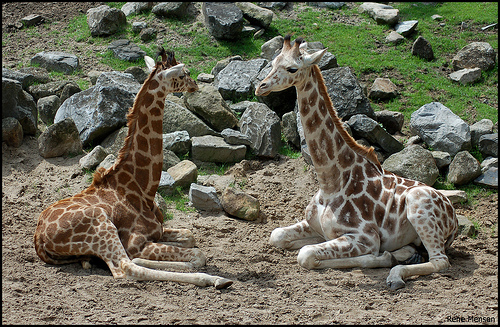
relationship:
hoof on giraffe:
[214, 276, 233, 291] [35, 47, 233, 290]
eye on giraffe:
[288, 67, 299, 73] [255, 37, 459, 290]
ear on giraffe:
[163, 63, 183, 78] [35, 47, 233, 290]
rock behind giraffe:
[167, 158, 197, 189] [35, 47, 233, 290]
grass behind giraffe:
[284, 14, 462, 74] [255, 37, 459, 290]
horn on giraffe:
[293, 37, 303, 52] [255, 37, 459, 290]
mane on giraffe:
[313, 64, 380, 165] [255, 37, 459, 290]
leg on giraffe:
[40, 212, 233, 288] [35, 47, 233, 290]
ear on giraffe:
[302, 47, 328, 65] [255, 37, 459, 290]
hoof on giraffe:
[388, 280, 407, 291] [255, 37, 459, 290]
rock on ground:
[167, 158, 197, 189] [3, 158, 500, 325]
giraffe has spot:
[35, 47, 233, 290] [136, 133, 149, 151]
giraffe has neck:
[35, 47, 233, 290] [110, 90, 166, 203]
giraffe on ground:
[255, 37, 459, 290] [3, 158, 500, 325]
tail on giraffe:
[34, 236, 93, 264] [35, 47, 233, 290]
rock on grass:
[409, 35, 434, 59] [284, 14, 462, 74]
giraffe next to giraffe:
[35, 47, 233, 290] [255, 37, 459, 290]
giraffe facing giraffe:
[35, 47, 233, 290] [255, 37, 459, 290]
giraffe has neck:
[255, 37, 459, 290] [298, 66, 384, 192]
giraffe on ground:
[35, 47, 233, 290] [3, 158, 500, 325]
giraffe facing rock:
[35, 47, 233, 290] [409, 35, 434, 59]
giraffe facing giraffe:
[255, 37, 459, 290] [35, 47, 233, 290]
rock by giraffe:
[222, 187, 260, 221] [35, 47, 233, 290]